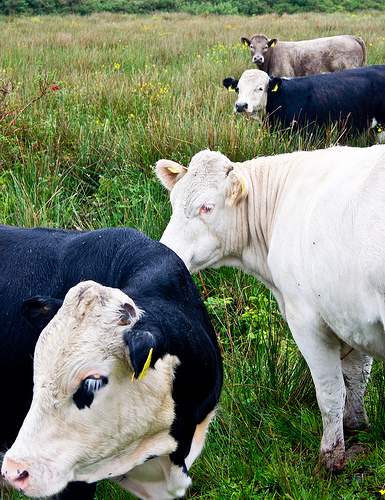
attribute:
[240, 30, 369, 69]
cow — brown, black, cattle, group , herd 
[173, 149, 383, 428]
cow — white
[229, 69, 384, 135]
cow — black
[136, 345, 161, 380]
tag — yellow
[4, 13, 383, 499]
grass — green, dead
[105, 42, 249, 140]
flower — yellow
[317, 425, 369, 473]
feet — white